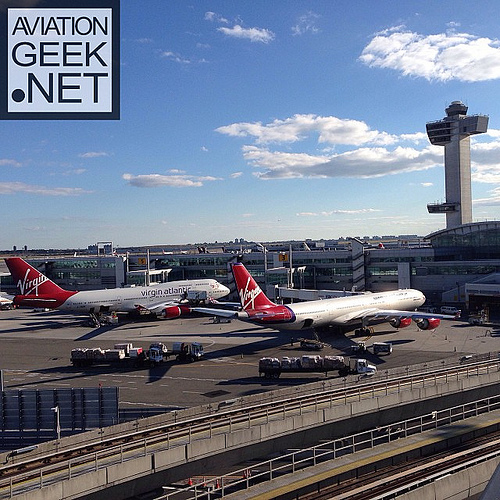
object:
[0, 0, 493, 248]
sky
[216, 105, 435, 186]
cloud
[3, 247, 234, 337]
plane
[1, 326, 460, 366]
tarmac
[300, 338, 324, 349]
trolley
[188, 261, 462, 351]
airport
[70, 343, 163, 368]
truck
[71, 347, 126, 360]
packages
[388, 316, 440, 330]
jet engines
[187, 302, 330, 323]
stabilizer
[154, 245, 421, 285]
passenger terminal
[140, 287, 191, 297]
name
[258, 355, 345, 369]
luggage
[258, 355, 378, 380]
cargo bay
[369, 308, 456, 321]
wing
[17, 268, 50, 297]
virgin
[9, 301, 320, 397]
runway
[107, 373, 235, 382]
lines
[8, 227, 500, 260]
back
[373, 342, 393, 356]
luggage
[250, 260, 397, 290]
windows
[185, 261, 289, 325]
tail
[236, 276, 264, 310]
word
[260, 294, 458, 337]
side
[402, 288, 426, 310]
nose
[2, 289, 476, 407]
land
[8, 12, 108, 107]
words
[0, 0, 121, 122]
left corner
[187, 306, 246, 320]
wing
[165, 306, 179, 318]
red